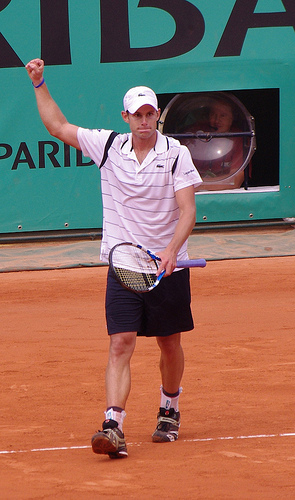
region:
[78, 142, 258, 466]
a man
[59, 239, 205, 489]
a man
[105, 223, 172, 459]
a man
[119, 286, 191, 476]
a man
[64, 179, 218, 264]
a man in white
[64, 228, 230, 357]
a man in white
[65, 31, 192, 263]
a man in white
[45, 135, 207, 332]
a man in white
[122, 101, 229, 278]
a man in white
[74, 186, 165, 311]
a man in white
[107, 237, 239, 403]
a man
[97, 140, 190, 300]
a man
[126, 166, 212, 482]
a man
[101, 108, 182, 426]
a man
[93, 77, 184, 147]
Man wearing white hat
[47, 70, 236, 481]
The man is walking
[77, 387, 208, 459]
Man wearing white and black shoes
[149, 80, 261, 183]
The man is sitting down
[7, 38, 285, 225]
Blue and black wall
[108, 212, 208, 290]
Purple tennis racket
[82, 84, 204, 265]
Man is wearing a striped shirt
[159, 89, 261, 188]
Man is sitting behind glass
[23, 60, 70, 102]
Man is wearing a blue bracelet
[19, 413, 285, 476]
Dirt with white lines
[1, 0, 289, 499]
a scene outside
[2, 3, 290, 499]
a scene happening during the day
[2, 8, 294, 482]
a tennis court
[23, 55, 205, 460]
a tennis player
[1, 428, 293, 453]
a white line on the court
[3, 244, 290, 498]
a tan dirt court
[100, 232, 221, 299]
a blue racket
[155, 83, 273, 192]
a person in the background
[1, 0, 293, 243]
a green cover in the background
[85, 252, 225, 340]
pair of black shorts